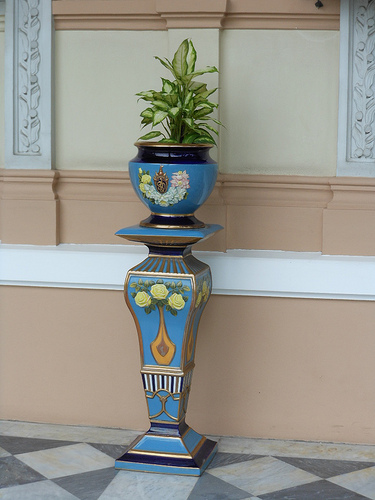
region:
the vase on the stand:
[127, 127, 219, 223]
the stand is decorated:
[115, 221, 244, 493]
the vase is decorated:
[122, 140, 226, 233]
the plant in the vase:
[141, 51, 225, 144]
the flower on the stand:
[133, 277, 194, 369]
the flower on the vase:
[138, 160, 212, 227]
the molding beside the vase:
[12, 0, 57, 158]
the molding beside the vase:
[330, 6, 373, 183]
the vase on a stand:
[113, 140, 226, 476]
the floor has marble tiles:
[4, 422, 374, 497]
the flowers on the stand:
[121, 273, 192, 323]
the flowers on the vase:
[133, 172, 190, 208]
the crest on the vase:
[156, 165, 173, 191]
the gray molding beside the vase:
[7, 17, 72, 172]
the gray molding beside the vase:
[336, 20, 374, 180]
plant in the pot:
[144, 37, 220, 174]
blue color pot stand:
[112, 225, 215, 498]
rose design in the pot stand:
[132, 275, 189, 354]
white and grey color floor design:
[230, 449, 363, 495]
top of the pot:
[132, 137, 219, 169]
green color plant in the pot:
[141, 40, 216, 144]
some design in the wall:
[343, 16, 373, 176]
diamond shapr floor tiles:
[209, 444, 324, 496]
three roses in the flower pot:
[128, 280, 190, 311]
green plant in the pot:
[150, 44, 213, 228]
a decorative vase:
[65, 37, 278, 491]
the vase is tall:
[112, 41, 245, 481]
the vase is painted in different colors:
[99, 24, 281, 492]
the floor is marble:
[6, 424, 373, 499]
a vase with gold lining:
[87, 115, 267, 484]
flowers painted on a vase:
[120, 271, 194, 318]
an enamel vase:
[91, 119, 305, 491]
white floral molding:
[8, 0, 66, 177]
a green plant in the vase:
[133, 27, 239, 166]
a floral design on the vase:
[130, 159, 200, 210]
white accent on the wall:
[0, 243, 372, 300]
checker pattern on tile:
[1, 421, 371, 496]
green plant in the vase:
[138, 38, 219, 144]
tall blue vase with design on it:
[114, 139, 218, 475]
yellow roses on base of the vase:
[132, 279, 209, 307]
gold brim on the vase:
[132, 139, 213, 148]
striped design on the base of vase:
[140, 370, 191, 390]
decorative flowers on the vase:
[136, 165, 189, 206]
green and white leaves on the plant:
[136, 37, 221, 143]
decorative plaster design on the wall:
[0, 0, 373, 175]